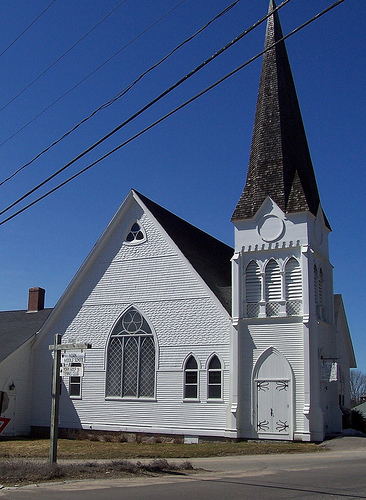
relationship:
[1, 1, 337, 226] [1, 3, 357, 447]
power lines are above church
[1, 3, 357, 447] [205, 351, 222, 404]
church has windows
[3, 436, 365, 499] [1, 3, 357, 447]
road in front of church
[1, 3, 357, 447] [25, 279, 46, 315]
church has chimney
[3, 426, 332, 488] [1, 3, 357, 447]
grass in front of church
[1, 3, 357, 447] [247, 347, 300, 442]
church has door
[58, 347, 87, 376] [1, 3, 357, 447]
sign outside of church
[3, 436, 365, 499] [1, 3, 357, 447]
road near church